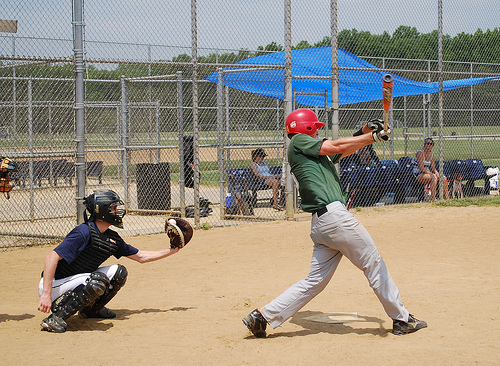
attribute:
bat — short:
[379, 76, 400, 145]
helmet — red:
[279, 101, 326, 137]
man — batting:
[239, 97, 435, 338]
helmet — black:
[82, 186, 123, 216]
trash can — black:
[133, 159, 174, 213]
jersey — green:
[282, 130, 347, 211]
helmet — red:
[279, 106, 326, 133]